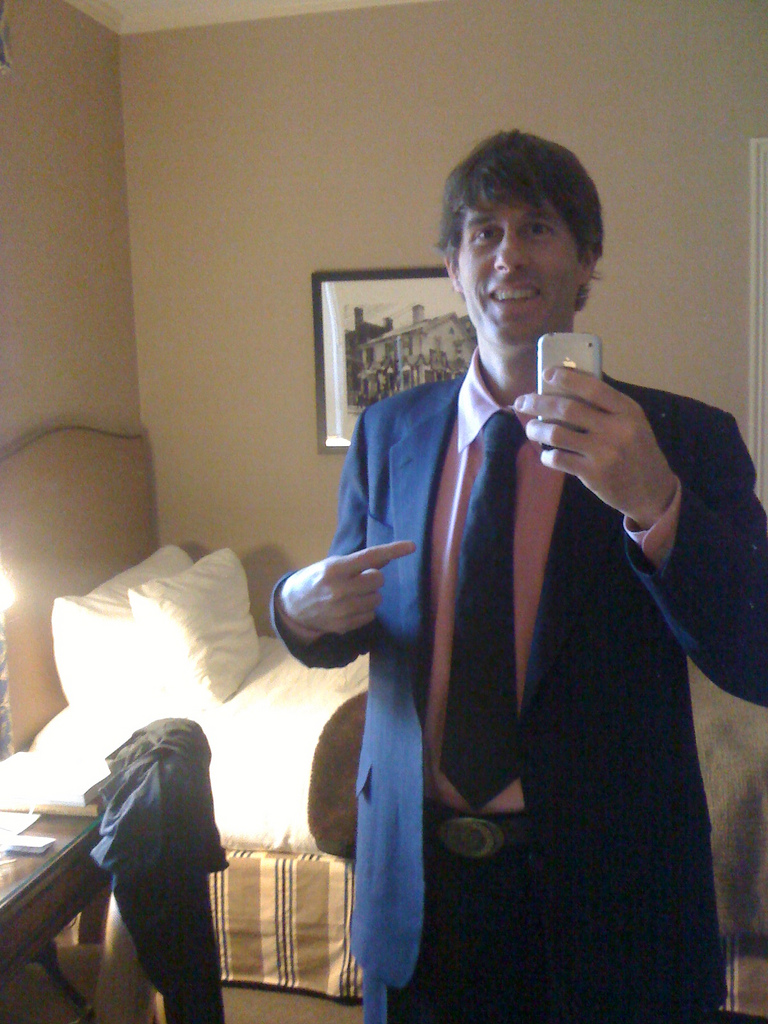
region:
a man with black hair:
[432, 132, 611, 330]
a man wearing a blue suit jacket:
[310, 127, 766, 966]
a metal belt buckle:
[427, 813, 511, 863]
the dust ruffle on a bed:
[192, 845, 367, 1002]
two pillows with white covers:
[46, 539, 256, 704]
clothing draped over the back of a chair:
[93, 721, 215, 1022]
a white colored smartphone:
[533, 331, 603, 403]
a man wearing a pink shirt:
[410, 126, 583, 839]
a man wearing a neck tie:
[441, 132, 519, 811]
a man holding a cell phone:
[434, 123, 655, 442]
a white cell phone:
[530, 319, 610, 425]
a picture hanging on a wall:
[310, 242, 442, 459]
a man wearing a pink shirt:
[388, 387, 550, 806]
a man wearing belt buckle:
[435, 818, 518, 860]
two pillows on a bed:
[43, 528, 260, 723]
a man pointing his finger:
[291, 532, 420, 648]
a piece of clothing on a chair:
[90, 709, 166, 1021]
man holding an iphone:
[266, 124, 765, 1022]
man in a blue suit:
[266, 127, 765, 1022]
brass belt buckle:
[436, 812, 509, 864]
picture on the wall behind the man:
[308, 260, 486, 456]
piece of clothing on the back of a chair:
[80, 710, 240, 1022]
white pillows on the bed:
[48, 538, 266, 732]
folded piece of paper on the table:
[1, 829, 61, 860]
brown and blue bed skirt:
[2, 804, 765, 1019]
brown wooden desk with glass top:
[0, 798, 130, 987]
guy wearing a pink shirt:
[265, 124, 765, 1019]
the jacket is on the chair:
[121, 720, 236, 1020]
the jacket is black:
[106, 725, 228, 1004]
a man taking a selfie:
[263, 114, 765, 1013]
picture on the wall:
[298, 254, 515, 455]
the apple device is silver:
[536, 330, 602, 450]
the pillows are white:
[47, 544, 260, 729]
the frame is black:
[309, 264, 480, 460]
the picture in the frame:
[309, 263, 477, 455]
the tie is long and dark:
[441, 411, 525, 814]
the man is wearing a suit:
[268, 128, 766, 1022]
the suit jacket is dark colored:
[267, 370, 765, 989]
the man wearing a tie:
[266, 132, 766, 1022]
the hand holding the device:
[511, 328, 675, 527]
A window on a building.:
[403, 335, 416, 353]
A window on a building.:
[375, 376, 380, 390]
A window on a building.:
[431, 336, 439, 350]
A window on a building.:
[453, 346, 462, 359]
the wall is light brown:
[26, 151, 351, 496]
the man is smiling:
[370, 204, 761, 930]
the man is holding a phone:
[495, 294, 718, 543]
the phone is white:
[490, 299, 650, 429]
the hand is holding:
[518, 354, 726, 554]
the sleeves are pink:
[522, 450, 693, 578]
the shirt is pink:
[449, 459, 591, 738]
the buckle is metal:
[383, 757, 578, 870]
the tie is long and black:
[441, 408, 523, 812]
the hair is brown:
[434, 128, 604, 314]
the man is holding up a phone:
[265, 130, 766, 1021]